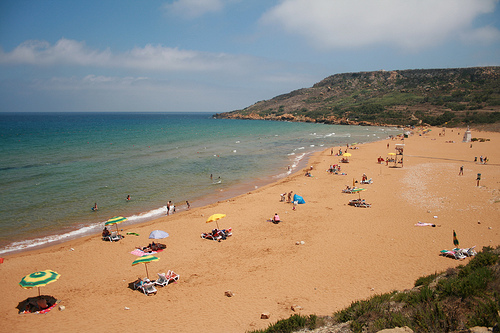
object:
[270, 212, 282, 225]
people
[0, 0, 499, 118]
sky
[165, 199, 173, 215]
person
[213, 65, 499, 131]
cliff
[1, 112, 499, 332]
beach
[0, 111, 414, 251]
water